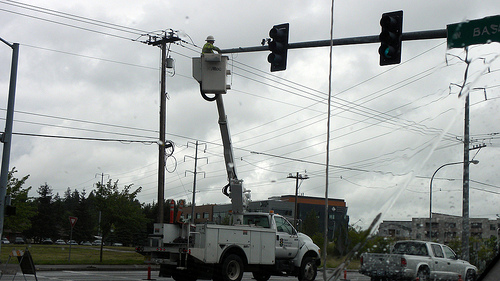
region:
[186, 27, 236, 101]
Man stand in crane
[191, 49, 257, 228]
Crane in a truck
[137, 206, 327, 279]
Truck is white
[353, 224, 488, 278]
Truck in front of crane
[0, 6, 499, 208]
Sky is full of clouds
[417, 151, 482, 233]
Street pole on left side of street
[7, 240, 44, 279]
Street sign behind crane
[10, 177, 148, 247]
Green trees in the background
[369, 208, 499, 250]
Buildings color brown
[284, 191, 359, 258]
Building with orange roof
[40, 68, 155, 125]
the sky is cloudy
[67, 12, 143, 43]
the wires are black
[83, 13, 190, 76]
wires are on poles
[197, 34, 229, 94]
worker in the box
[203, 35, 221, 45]
the hat is white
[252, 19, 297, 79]
signal light is black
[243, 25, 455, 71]
two signal lights on post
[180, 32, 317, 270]
basket is above truck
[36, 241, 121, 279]
the grass is green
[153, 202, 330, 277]
the work truck is white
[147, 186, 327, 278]
the truck is white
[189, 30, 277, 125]
the man is fixing the stop light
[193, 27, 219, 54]
the man is wearing a helmet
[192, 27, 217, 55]
the helmet is white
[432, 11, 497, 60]
the sign is green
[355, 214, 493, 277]
the truck is gray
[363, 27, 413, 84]
the light is green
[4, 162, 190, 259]
the trees are green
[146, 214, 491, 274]
the trucks are in the street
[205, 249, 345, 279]
the truck's tires are black and gray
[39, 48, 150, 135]
the sky is gray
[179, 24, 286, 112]
man is repairing the stop light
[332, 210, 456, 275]
the truck is silver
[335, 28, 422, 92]
the light is green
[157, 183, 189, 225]
the cones are orange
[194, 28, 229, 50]
man is wearing hard hat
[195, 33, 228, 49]
hard hat is white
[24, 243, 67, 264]
the grass is green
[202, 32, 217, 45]
the head of a man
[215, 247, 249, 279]
a wheel on the truck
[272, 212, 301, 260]
a door on the truck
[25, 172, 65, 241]
a green tree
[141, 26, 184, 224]
a brown telephone pole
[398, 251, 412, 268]
a red tail light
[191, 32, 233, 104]
a white metal basket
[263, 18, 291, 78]
a bank of traffic lights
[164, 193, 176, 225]
an orange and white traffic marker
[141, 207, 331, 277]
a white truck